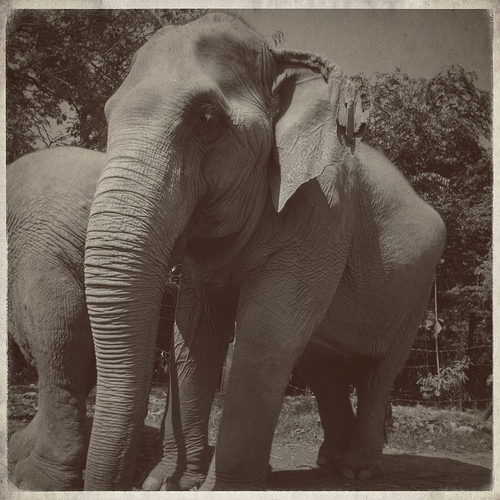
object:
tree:
[7, 7, 203, 147]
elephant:
[77, 12, 452, 494]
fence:
[159, 274, 496, 407]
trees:
[5, 9, 498, 402]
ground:
[0, 379, 494, 500]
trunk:
[79, 129, 207, 495]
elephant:
[3, 145, 105, 489]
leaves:
[419, 357, 473, 407]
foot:
[315, 435, 347, 472]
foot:
[337, 440, 386, 483]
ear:
[262, 46, 367, 218]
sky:
[233, 8, 493, 82]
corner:
[8, 11, 109, 137]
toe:
[341, 465, 355, 483]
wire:
[411, 343, 495, 355]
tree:
[350, 60, 489, 346]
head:
[76, 10, 339, 253]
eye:
[192, 99, 230, 140]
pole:
[431, 271, 444, 375]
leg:
[144, 275, 219, 493]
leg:
[200, 271, 319, 491]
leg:
[295, 354, 355, 470]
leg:
[340, 372, 395, 484]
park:
[1, 255, 491, 490]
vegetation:
[8, 381, 496, 457]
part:
[389, 449, 484, 487]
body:
[268, 135, 449, 372]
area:
[7, 264, 491, 409]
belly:
[295, 140, 457, 380]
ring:
[345, 99, 359, 148]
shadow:
[267, 450, 494, 489]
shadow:
[82, 414, 164, 491]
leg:
[12, 258, 85, 490]